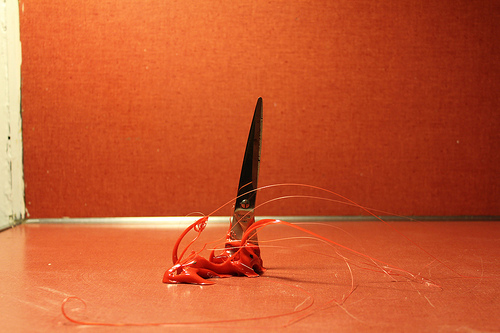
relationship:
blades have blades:
[235, 96, 266, 208] [235, 96, 266, 208]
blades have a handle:
[235, 96, 266, 208] [63, 182, 445, 328]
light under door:
[27, 216, 231, 223] [21, 4, 499, 218]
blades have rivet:
[235, 96, 266, 208] [241, 199, 251, 208]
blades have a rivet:
[235, 96, 266, 208] [241, 199, 251, 208]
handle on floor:
[63, 182, 445, 328] [1, 218, 500, 331]